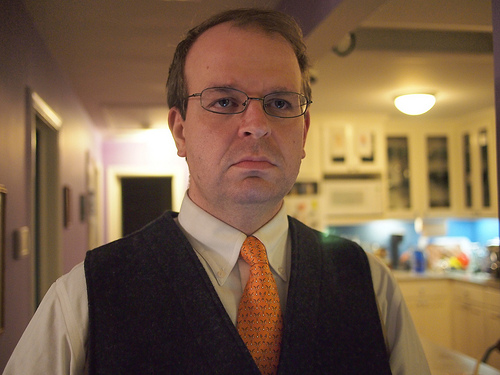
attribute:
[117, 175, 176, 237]
doorway — dark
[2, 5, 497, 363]
room — dark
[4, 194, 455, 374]
shirt — white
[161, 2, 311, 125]
hair — short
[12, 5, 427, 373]
man — black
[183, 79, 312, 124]
glasses — reading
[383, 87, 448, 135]
light — illuminating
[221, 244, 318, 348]
tie — yellow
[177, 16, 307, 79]
hairline — receding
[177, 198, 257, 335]
collard shirt — white, collared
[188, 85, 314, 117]
eyeglasses — metal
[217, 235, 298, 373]
tie — orange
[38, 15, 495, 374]
man — white, oxford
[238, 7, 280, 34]
hair — blonde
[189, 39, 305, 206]
face — fresh, shaved